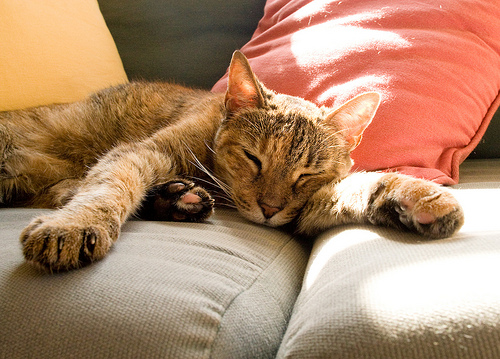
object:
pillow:
[208, 0, 497, 185]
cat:
[2, 49, 464, 272]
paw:
[383, 178, 465, 239]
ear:
[223, 50, 270, 111]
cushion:
[1, 202, 310, 358]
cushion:
[273, 158, 499, 359]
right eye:
[297, 167, 326, 185]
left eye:
[242, 146, 264, 177]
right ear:
[321, 91, 381, 154]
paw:
[16, 218, 116, 279]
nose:
[261, 202, 283, 218]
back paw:
[139, 176, 216, 221]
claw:
[88, 234, 96, 245]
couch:
[0, 0, 499, 357]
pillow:
[2, 0, 130, 115]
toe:
[181, 192, 203, 204]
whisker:
[174, 137, 240, 210]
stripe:
[288, 127, 307, 155]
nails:
[43, 233, 97, 249]